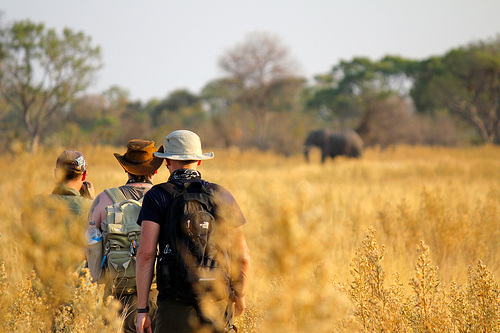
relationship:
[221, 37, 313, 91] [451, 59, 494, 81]
tree without leaves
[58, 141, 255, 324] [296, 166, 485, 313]
men in field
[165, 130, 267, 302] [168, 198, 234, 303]
man with backpack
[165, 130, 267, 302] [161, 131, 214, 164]
man has hat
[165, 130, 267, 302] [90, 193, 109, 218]
man has tattoo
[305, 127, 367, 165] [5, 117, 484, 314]
elephant on plain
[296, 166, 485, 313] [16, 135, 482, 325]
grass on plain